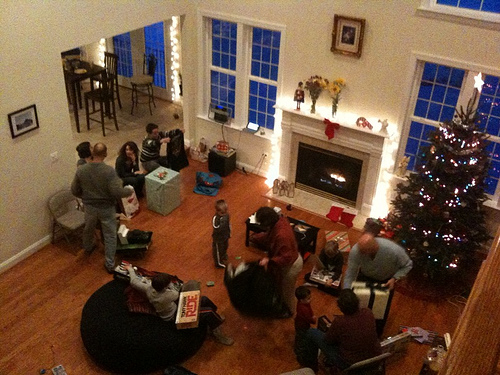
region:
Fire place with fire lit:
[268, 105, 386, 217]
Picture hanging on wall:
[325, 7, 370, 65]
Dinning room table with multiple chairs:
[60, 45, 157, 135]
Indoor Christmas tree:
[380, 62, 486, 297]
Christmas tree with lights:
[385, 68, 488, 303]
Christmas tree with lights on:
[378, 65, 486, 295]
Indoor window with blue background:
[195, 7, 288, 139]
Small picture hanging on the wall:
[3, 103, 50, 139]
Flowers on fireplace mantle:
[282, 70, 395, 145]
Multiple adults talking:
[68, 118, 196, 270]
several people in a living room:
[55, 114, 402, 339]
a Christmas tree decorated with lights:
[390, 58, 490, 288]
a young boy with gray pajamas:
[206, 195, 236, 270]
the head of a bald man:
[356, 232, 378, 262]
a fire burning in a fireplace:
[288, 133, 367, 206]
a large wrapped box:
[140, 163, 189, 215]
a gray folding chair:
[38, 186, 88, 253]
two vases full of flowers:
[306, 73, 346, 118]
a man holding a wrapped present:
[339, 228, 414, 326]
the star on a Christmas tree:
[466, 63, 493, 91]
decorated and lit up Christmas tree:
[396, 70, 487, 242]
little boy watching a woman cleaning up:
[211, 199, 233, 269]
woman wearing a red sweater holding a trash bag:
[255, 207, 302, 279]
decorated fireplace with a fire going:
[272, 74, 393, 209]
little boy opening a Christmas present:
[307, 239, 343, 291]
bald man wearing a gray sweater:
[343, 233, 411, 290]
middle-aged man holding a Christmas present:
[344, 233, 411, 294]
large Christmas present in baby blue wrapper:
[144, 165, 181, 217]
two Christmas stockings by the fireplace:
[326, 200, 358, 227]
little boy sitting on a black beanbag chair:
[121, 261, 179, 321]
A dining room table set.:
[64, 50, 129, 128]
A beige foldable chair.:
[49, 191, 94, 253]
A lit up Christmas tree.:
[364, 86, 497, 298]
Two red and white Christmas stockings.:
[325, 200, 360, 230]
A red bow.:
[319, 115, 342, 139]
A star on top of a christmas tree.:
[468, 69, 488, 96]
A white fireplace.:
[273, 104, 393, 216]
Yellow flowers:
[323, 72, 345, 113]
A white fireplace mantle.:
[283, 73, 398, 145]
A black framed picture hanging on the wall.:
[10, 103, 41, 142]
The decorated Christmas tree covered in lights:
[391, 63, 488, 299]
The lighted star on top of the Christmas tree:
[475, 73, 482, 92]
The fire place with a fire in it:
[268, 108, 388, 232]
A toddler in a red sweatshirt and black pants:
[295, 289, 315, 348]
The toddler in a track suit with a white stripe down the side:
[213, 204, 228, 269]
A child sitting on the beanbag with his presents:
[78, 260, 223, 371]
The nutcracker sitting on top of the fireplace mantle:
[293, 82, 305, 110]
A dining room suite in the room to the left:
[65, 58, 162, 135]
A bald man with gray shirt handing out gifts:
[347, 229, 411, 335]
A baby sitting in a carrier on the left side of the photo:
[106, 215, 155, 252]